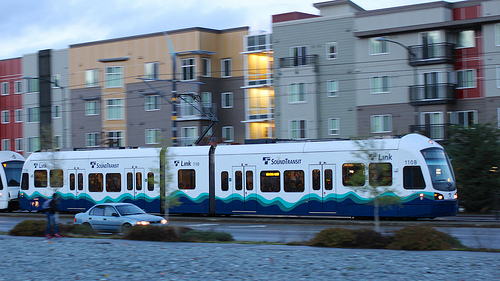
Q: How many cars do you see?
A: One car.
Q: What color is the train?
A: White,teal and blue.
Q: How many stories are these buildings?
A: Four.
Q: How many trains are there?
A: One.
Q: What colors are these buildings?
A: Tan,grey and red.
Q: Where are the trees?
A: Next to the road.